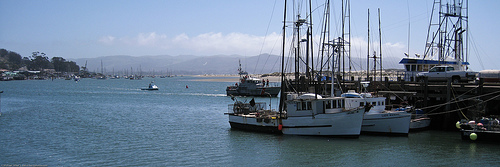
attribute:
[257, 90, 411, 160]
boats — large, white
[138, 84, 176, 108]
boat — small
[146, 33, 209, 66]
clouds — distant, low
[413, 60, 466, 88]
truck — white, parked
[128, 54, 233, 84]
mountains — white, distant, misty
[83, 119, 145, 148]
water — calm, blue, pleasant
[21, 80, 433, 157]
water — blue, still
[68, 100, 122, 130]
water — blue, still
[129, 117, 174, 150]
water — still, blue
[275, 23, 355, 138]
boat — white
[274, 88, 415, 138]
boats — next to each other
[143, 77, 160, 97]
boat — small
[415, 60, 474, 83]
vehicle — white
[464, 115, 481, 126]
floats — colorful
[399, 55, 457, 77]
building — flat, low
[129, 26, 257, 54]
clouds — white 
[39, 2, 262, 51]
sky — light blue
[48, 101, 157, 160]
water — above 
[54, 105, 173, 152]
water — blue 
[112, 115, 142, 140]
ripples — little 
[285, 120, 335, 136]
stripe — black 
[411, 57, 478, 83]
truck — silver pickup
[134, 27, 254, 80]
mountains — background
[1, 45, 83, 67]
trees — background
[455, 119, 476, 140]
things — green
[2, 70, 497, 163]
water — blue 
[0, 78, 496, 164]
water — blue 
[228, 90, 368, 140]
boat — white 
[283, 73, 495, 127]
dock — wooden 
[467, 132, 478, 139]
ball — yellow 